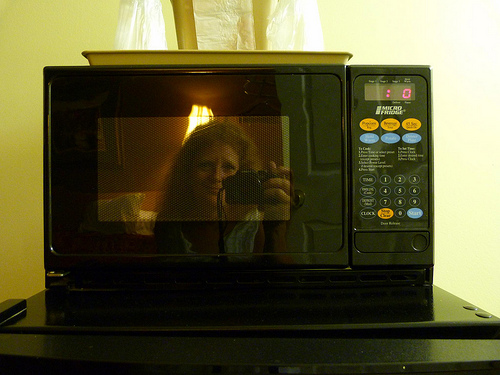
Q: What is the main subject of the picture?
A: A microwave.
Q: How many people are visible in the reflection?
A: One.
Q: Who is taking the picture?
A: The woman.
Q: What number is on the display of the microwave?
A: Zero.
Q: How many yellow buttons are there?
A: Four.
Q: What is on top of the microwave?
A: A tray.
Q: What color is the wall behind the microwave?
A: Tan.